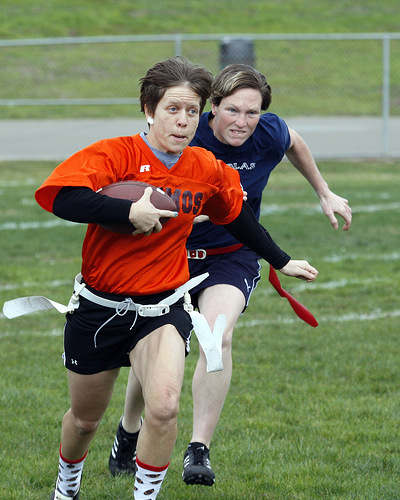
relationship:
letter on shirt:
[141, 161, 155, 175] [38, 134, 242, 295]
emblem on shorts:
[70, 356, 80, 369] [59, 278, 197, 375]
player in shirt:
[27, 49, 320, 493] [38, 134, 242, 295]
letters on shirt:
[151, 186, 204, 218] [38, 134, 242, 295]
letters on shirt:
[226, 157, 258, 173] [174, 109, 293, 256]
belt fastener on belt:
[185, 251, 209, 260] [187, 236, 321, 339]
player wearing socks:
[34, 54, 320, 500] [53, 449, 174, 496]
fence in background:
[3, 30, 400, 159] [3, 0, 397, 179]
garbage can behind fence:
[214, 38, 261, 74] [3, 30, 400, 159]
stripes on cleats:
[106, 441, 217, 471] [109, 417, 225, 488]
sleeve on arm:
[52, 182, 133, 229] [34, 134, 160, 250]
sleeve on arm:
[226, 204, 292, 275] [190, 134, 293, 284]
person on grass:
[35, 56, 332, 495] [0, 8, 395, 496]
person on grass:
[101, 58, 359, 487] [0, 8, 395, 496]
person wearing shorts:
[35, 56, 332, 495] [59, 278, 197, 375]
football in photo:
[92, 182, 177, 228] [6, 12, 400, 494]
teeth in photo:
[229, 128, 247, 134] [6, 12, 400, 494]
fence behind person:
[3, 30, 400, 159] [35, 56, 332, 495]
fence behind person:
[3, 30, 400, 159] [101, 58, 359, 487]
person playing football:
[35, 56, 332, 495] [7, 4, 397, 492]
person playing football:
[101, 58, 359, 487] [92, 182, 177, 228]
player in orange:
[27, 49, 320, 493] [37, 136, 251, 291]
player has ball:
[27, 49, 320, 493] [92, 182, 177, 228]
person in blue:
[101, 58, 359, 487] [168, 107, 293, 304]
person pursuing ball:
[101, 58, 359, 487] [92, 182, 177, 228]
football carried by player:
[92, 182, 177, 228] [27, 49, 320, 493]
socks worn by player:
[53, 449, 174, 496] [27, 49, 320, 493]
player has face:
[27, 49, 320, 493] [154, 83, 209, 152]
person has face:
[101, 58, 359, 487] [213, 83, 268, 149]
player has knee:
[27, 49, 320, 493] [141, 384, 183, 426]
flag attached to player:
[190, 308, 232, 386] [27, 49, 320, 493]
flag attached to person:
[264, 261, 325, 334] [101, 58, 359, 487]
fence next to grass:
[3, 30, 400, 159] [0, 8, 395, 496]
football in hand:
[92, 182, 177, 228] [128, 186, 182, 238]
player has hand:
[27, 49, 320, 493] [128, 186, 182, 238]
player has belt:
[27, 49, 320, 493] [69, 268, 215, 323]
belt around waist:
[69, 268, 215, 323] [75, 276, 189, 305]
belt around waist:
[187, 236, 321, 339] [185, 238, 259, 263]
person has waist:
[101, 58, 359, 487] [185, 238, 259, 263]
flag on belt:
[190, 308, 232, 386] [69, 268, 215, 323]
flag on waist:
[190, 308, 232, 386] [185, 238, 259, 263]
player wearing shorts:
[27, 49, 320, 493] [59, 278, 197, 375]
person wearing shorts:
[101, 58, 359, 487] [174, 243, 262, 309]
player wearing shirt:
[27, 49, 320, 493] [38, 134, 242, 295]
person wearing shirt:
[101, 58, 359, 487] [174, 109, 293, 256]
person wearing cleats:
[101, 58, 359, 487] [109, 417, 225, 488]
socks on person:
[53, 449, 174, 496] [35, 56, 353, 500]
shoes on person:
[110, 422, 218, 484] [101, 58, 359, 487]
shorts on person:
[59, 278, 197, 375] [35, 56, 353, 500]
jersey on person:
[24, 136, 248, 296] [35, 56, 353, 500]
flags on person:
[1, 290, 232, 371] [35, 56, 353, 500]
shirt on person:
[174, 109, 293, 256] [101, 58, 359, 487]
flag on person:
[264, 261, 325, 334] [101, 58, 359, 487]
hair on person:
[139, 56, 218, 115] [35, 56, 353, 500]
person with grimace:
[35, 56, 332, 495] [166, 98, 200, 143]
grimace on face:
[166, 98, 200, 143] [154, 83, 209, 152]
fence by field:
[3, 30, 400, 159] [4, 6, 400, 122]